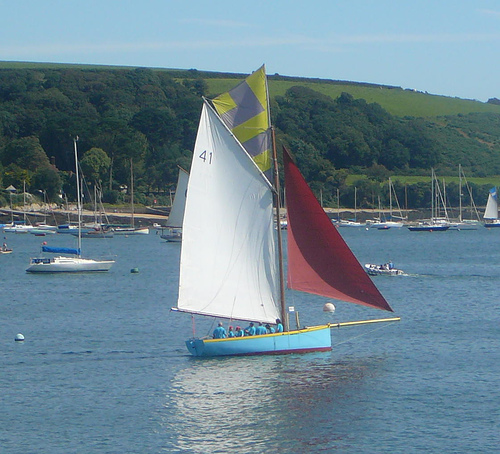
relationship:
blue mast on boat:
[38, 238, 84, 258] [25, 129, 115, 276]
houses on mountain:
[374, 79, 433, 100] [5, 49, 496, 186]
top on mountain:
[2, 51, 492, 118] [5, 49, 496, 186]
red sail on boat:
[280, 147, 395, 312] [165, 60, 405, 363]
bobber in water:
[14, 328, 28, 341] [0, 217, 496, 452]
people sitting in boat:
[208, 322, 293, 338] [182, 322, 336, 358]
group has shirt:
[209, 322, 226, 340] [214, 329, 224, 336]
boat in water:
[173, 66, 403, 350] [0, 347, 499, 450]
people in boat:
[271, 316, 287, 333] [173, 66, 403, 350]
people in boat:
[257, 321, 267, 336] [173, 66, 403, 350]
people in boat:
[228, 328, 234, 337] [173, 66, 403, 350]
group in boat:
[209, 322, 226, 340] [173, 66, 403, 350]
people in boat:
[245, 321, 256, 335] [173, 66, 403, 350]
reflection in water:
[180, 355, 282, 433] [0, 217, 496, 452]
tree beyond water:
[77, 145, 112, 202] [0, 217, 496, 452]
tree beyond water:
[116, 125, 148, 190] [0, 217, 496, 452]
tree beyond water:
[131, 110, 177, 146] [0, 217, 496, 452]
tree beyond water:
[32, 164, 64, 204] [0, 217, 496, 452]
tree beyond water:
[178, 117, 196, 138] [0, 217, 496, 452]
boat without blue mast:
[25, 129, 115, 276] [39, 244, 80, 254]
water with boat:
[0, 217, 496, 452] [397, 163, 456, 234]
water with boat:
[0, 217, 496, 452] [18, 133, 118, 271]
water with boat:
[0, 217, 496, 452] [165, 60, 405, 363]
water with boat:
[0, 217, 496, 452] [52, 129, 117, 242]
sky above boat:
[2, 3, 498, 103] [173, 66, 413, 352]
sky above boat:
[2, 3, 498, 103] [18, 133, 118, 271]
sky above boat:
[2, 3, 498, 103] [153, 162, 198, 243]